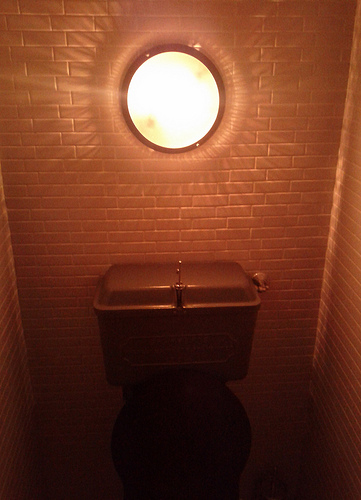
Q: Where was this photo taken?
A: Bathroom.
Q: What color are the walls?
A: Orange.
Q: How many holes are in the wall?
A: One.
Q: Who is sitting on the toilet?
A: No one.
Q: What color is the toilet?
A: Brown.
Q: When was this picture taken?
A: Daytime.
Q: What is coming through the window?
A: Sunlight.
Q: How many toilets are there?
A: One.